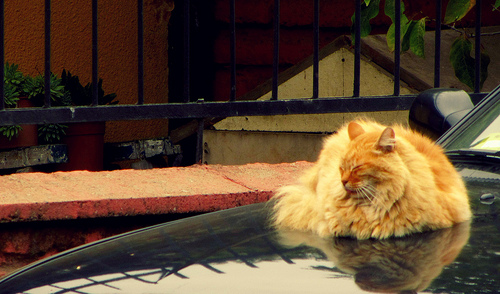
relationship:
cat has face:
[275, 117, 474, 240] [329, 157, 378, 199]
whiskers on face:
[353, 179, 384, 206] [329, 157, 378, 199]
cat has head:
[275, 117, 474, 240] [332, 116, 411, 199]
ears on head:
[346, 117, 400, 154] [332, 116, 411, 199]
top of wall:
[1, 162, 312, 216] [0, 210, 183, 270]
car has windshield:
[15, 82, 500, 291] [438, 83, 499, 163]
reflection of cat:
[301, 224, 473, 293] [275, 117, 474, 240]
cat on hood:
[275, 117, 474, 240] [1, 183, 500, 292]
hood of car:
[1, 183, 500, 292] [15, 82, 500, 291]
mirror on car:
[406, 85, 474, 135] [15, 82, 500, 291]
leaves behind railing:
[6, 66, 40, 95] [1, 1, 499, 119]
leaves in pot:
[0, 61, 120, 145] [43, 121, 107, 171]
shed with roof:
[178, 27, 493, 161] [332, 25, 498, 90]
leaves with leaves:
[0, 61, 120, 145] [6, 66, 40, 95]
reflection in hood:
[301, 224, 473, 293] [1, 183, 500, 292]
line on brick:
[60, 234, 63, 242] [34, 221, 106, 254]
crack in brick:
[50, 231, 62, 250] [34, 221, 106, 254]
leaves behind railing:
[0, 61, 120, 145] [1, 1, 499, 119]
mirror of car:
[406, 85, 474, 135] [15, 82, 500, 291]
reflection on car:
[44, 257, 351, 293] [15, 82, 500, 291]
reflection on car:
[301, 224, 473, 293] [15, 82, 500, 291]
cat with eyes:
[275, 117, 474, 240] [336, 162, 368, 172]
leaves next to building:
[0, 61, 120, 145] [4, 2, 343, 154]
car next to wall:
[15, 82, 500, 291] [0, 210, 183, 270]